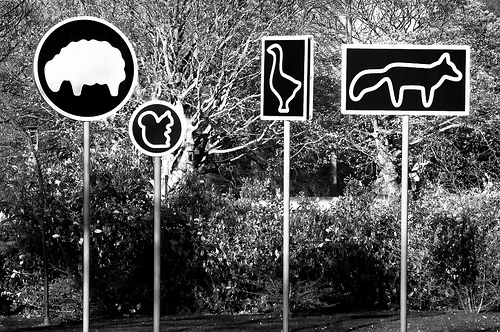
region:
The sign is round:
[21, 19, 138, 121]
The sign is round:
[122, 93, 188, 161]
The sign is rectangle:
[257, 30, 311, 120]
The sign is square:
[333, 38, 485, 132]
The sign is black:
[18, 12, 148, 128]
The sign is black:
[126, 98, 188, 159]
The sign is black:
[254, 33, 315, 131]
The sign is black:
[340, 36, 468, 121]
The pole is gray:
[71, 112, 103, 328]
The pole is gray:
[141, 150, 170, 330]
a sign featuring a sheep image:
[35, 16, 137, 331]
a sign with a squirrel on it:
[128, 99, 185, 331]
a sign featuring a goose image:
[260, 36, 312, 330]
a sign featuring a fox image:
[339, 42, 469, 330]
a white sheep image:
[40, 39, 125, 95]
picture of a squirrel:
[139, 109, 174, 147]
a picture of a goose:
[265, 42, 301, 112]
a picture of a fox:
[348, 52, 463, 106]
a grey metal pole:
[81, 121, 90, 331]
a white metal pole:
[282, 123, 290, 330]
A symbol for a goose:
[265, 40, 300, 111]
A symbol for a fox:
[351, 65, 463, 115]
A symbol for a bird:
[125, 105, 172, 140]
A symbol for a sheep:
[40, 45, 130, 105]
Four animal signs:
[31, 6, 471, 156]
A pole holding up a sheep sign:
[70, 120, 101, 327]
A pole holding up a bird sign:
[151, 166, 171, 326]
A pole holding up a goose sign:
[280, 116, 300, 326]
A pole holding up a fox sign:
[400, 107, 420, 327]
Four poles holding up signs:
[80, 120, 415, 330]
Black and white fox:
[349, 50, 462, 106]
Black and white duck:
[266, 42, 303, 114]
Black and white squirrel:
[137, 109, 174, 148]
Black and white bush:
[189, 174, 340, 317]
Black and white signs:
[33, 15, 470, 155]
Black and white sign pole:
[400, 117, 409, 330]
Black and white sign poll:
[282, 119, 289, 330]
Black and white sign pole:
[154, 156, 160, 330]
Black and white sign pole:
[83, 120, 88, 330]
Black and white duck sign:
[262, 36, 314, 121]